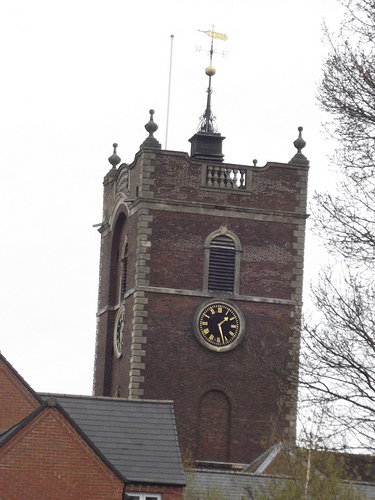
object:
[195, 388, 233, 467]
arch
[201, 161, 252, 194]
railing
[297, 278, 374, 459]
tree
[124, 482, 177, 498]
top window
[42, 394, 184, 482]
roof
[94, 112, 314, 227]
roof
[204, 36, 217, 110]
vane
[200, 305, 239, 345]
roman numberals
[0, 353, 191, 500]
building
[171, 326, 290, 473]
wall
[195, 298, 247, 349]
black clock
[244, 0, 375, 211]
clouds sky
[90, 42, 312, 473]
clock tower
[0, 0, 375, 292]
sky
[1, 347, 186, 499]
house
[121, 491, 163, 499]
window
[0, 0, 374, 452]
cloud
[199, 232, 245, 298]
window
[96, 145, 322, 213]
top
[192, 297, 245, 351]
time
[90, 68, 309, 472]
tower